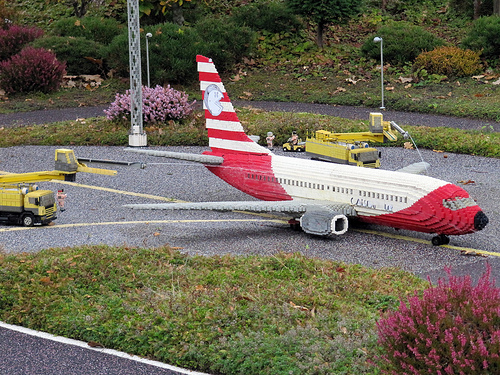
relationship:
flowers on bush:
[402, 292, 467, 353] [105, 82, 196, 130]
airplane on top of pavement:
[125, 53, 488, 249] [2, 145, 498, 291]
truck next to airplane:
[303, 111, 406, 172] [125, 53, 488, 249]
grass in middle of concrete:
[1, 108, 500, 157] [2, 99, 500, 293]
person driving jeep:
[288, 131, 298, 146] [281, 141, 306, 153]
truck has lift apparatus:
[303, 111, 406, 172] [323, 113, 396, 142]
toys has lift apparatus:
[1, 143, 119, 232] [2, 150, 115, 190]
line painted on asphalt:
[1, 323, 212, 374] [0, 322, 222, 373]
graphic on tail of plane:
[202, 84, 226, 116] [125, 53, 488, 249]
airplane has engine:
[125, 53, 488, 249] [296, 207, 349, 236]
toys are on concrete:
[1, 44, 488, 248] [2, 99, 500, 293]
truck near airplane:
[303, 111, 406, 172] [125, 53, 488, 249]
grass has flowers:
[1, 108, 500, 157] [105, 82, 196, 130]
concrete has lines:
[2, 99, 500, 293] [0, 169, 498, 263]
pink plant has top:
[105, 82, 196, 130] [116, 83, 185, 99]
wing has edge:
[123, 201, 354, 211] [129, 205, 348, 213]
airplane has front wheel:
[125, 53, 488, 249] [434, 235, 449, 247]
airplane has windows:
[125, 53, 488, 249] [243, 172, 409, 203]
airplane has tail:
[125, 53, 488, 249] [194, 53, 277, 156]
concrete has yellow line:
[2, 99, 500, 293] [0, 169, 498, 263]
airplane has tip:
[125, 53, 488, 249] [476, 210, 488, 232]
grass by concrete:
[1, 108, 500, 157] [2, 99, 500, 293]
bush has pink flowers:
[105, 82, 196, 130] [104, 83, 196, 125]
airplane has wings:
[125, 53, 488, 249] [120, 145, 431, 233]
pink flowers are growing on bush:
[104, 83, 196, 125] [105, 82, 196, 130]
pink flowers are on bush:
[104, 83, 196, 125] [105, 82, 196, 130]